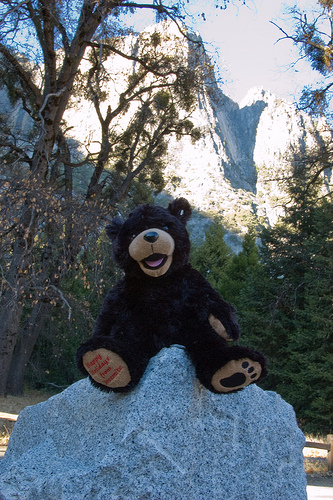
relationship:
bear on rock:
[77, 183, 265, 431] [11, 349, 303, 487]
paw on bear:
[210, 345, 270, 412] [81, 197, 294, 429]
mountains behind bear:
[11, 15, 321, 244] [77, 183, 265, 431]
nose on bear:
[142, 221, 158, 244] [77, 183, 265, 431]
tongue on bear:
[143, 254, 166, 274] [77, 183, 265, 431]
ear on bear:
[162, 189, 207, 233] [77, 183, 265, 431]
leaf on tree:
[285, 333, 328, 406] [199, 214, 318, 372]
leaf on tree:
[302, 387, 317, 423] [265, 213, 321, 448]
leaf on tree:
[285, 333, 328, 406] [248, 222, 317, 439]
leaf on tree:
[285, 333, 328, 406] [250, 254, 311, 409]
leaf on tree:
[285, 333, 328, 406] [257, 184, 319, 428]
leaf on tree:
[285, 333, 328, 406] [253, 225, 315, 418]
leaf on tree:
[285, 333, 328, 406] [232, 208, 311, 419]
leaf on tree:
[285, 333, 328, 406] [265, 230, 321, 434]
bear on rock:
[77, 183, 265, 431] [4, 346, 317, 498]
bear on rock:
[77, 183, 265, 431] [7, 332, 317, 494]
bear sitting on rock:
[77, 183, 265, 431] [7, 332, 317, 494]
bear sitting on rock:
[77, 183, 265, 431] [0, 340, 332, 496]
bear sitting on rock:
[77, 183, 265, 431] [4, 346, 317, 498]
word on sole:
[101, 363, 126, 390] [78, 345, 133, 389]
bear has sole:
[77, 183, 265, 431] [78, 345, 133, 389]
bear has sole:
[77, 183, 265, 431] [74, 343, 133, 392]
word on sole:
[101, 363, 126, 390] [74, 343, 133, 392]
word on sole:
[101, 363, 126, 390] [76, 346, 138, 392]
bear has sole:
[77, 183, 265, 431] [76, 346, 138, 392]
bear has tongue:
[77, 183, 265, 431] [143, 254, 166, 274]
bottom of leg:
[79, 347, 134, 388] [73, 312, 159, 394]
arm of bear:
[188, 279, 243, 342] [77, 183, 265, 431]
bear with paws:
[77, 183, 265, 431] [74, 346, 264, 393]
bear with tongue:
[77, 183, 265, 431] [140, 254, 164, 267]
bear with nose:
[77, 183, 265, 431] [144, 228, 161, 241]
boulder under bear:
[1, 336, 309, 497] [77, 183, 265, 431]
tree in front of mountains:
[216, 210, 269, 366] [11, 15, 321, 244]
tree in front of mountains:
[216, 210, 269, 366] [0, 15, 331, 234]